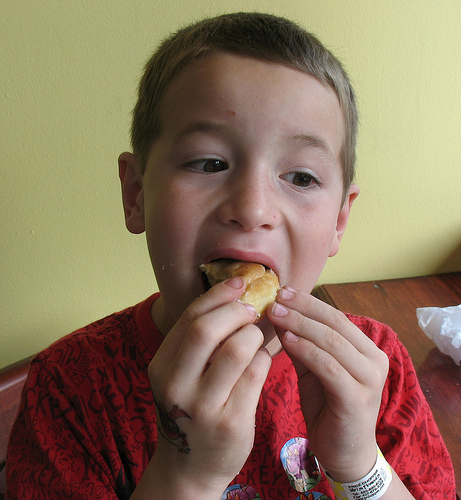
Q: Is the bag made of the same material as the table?
A: No, the bag is made of plastic and the table is made of wood.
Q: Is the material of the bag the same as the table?
A: No, the bag is made of plastic and the table is made of wood.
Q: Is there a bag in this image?
A: Yes, there is a bag.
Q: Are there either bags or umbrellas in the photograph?
A: Yes, there is a bag.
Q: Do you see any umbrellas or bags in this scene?
A: Yes, there is a bag.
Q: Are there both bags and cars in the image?
A: No, there is a bag but no cars.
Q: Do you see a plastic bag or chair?
A: Yes, there is a plastic bag.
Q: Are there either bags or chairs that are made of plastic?
A: Yes, the bag is made of plastic.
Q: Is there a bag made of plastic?
A: Yes, there is a bag that is made of plastic.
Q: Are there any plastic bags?
A: Yes, there is a bag that is made of plastic.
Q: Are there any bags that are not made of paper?
A: Yes, there is a bag that is made of plastic.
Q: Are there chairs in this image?
A: No, there are no chairs.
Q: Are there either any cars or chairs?
A: No, there are no chairs or cars.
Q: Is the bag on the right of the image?
A: Yes, the bag is on the right of the image.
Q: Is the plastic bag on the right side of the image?
A: Yes, the bag is on the right of the image.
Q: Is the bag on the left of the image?
A: No, the bag is on the right of the image.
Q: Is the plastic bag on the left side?
A: No, the bag is on the right of the image.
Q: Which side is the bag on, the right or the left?
A: The bag is on the right of the image.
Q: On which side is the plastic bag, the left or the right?
A: The bag is on the right of the image.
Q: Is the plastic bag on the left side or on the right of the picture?
A: The bag is on the right of the image.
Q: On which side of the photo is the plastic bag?
A: The bag is on the right of the image.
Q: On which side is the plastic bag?
A: The bag is on the right of the image.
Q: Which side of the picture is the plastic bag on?
A: The bag is on the right of the image.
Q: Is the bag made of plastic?
A: Yes, the bag is made of plastic.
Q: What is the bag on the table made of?
A: The bag is made of plastic.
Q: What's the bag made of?
A: The bag is made of plastic.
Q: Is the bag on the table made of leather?
A: No, the bag is made of plastic.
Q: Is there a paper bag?
A: No, there is a bag but it is made of plastic.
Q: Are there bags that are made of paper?
A: No, there is a bag but it is made of plastic.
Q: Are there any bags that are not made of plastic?
A: No, there is a bag but it is made of plastic.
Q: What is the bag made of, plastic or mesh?
A: The bag is made of plastic.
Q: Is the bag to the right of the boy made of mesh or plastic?
A: The bag is made of plastic.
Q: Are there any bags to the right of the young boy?
A: Yes, there is a bag to the right of the boy.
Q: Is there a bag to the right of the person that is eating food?
A: Yes, there is a bag to the right of the boy.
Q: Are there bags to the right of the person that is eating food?
A: Yes, there is a bag to the right of the boy.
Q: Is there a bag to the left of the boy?
A: No, the bag is to the right of the boy.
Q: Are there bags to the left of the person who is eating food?
A: No, the bag is to the right of the boy.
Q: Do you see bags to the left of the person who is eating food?
A: No, the bag is to the right of the boy.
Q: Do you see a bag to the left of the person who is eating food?
A: No, the bag is to the right of the boy.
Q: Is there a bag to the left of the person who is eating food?
A: No, the bag is to the right of the boy.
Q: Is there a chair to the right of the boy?
A: No, there is a bag to the right of the boy.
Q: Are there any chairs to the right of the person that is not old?
A: No, there is a bag to the right of the boy.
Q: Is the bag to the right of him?
A: Yes, the bag is to the right of the boy.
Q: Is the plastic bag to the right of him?
A: Yes, the bag is to the right of the boy.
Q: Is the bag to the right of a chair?
A: No, the bag is to the right of the boy.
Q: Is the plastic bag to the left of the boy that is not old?
A: No, the bag is to the right of the boy.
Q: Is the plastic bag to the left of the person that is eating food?
A: No, the bag is to the right of the boy.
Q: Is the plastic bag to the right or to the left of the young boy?
A: The bag is to the right of the boy.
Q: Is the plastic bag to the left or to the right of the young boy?
A: The bag is to the right of the boy.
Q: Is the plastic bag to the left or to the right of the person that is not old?
A: The bag is to the right of the boy.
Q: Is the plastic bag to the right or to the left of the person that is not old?
A: The bag is to the right of the boy.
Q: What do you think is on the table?
A: The bag is on the table.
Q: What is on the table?
A: The bag is on the table.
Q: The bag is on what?
A: The bag is on the table.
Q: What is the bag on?
A: The bag is on the table.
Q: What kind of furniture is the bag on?
A: The bag is on the table.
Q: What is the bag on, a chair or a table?
A: The bag is on a table.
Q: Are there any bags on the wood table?
A: Yes, there is a bag on the table.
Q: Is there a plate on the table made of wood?
A: No, there is a bag on the table.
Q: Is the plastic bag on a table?
A: Yes, the bag is on a table.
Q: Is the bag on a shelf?
A: No, the bag is on a table.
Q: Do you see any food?
A: Yes, there is food.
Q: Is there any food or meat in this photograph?
A: Yes, there is food.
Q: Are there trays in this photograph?
A: No, there are no trays.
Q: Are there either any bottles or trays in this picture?
A: No, there are no trays or bottles.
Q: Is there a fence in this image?
A: No, there are no fences.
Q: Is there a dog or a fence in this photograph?
A: No, there are no fences or dogs.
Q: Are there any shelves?
A: No, there are no shelves.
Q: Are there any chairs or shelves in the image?
A: No, there are no shelves or chairs.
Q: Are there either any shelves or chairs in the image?
A: No, there are no shelves or chairs.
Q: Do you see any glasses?
A: No, there are no glasses.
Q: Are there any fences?
A: No, there are no fences.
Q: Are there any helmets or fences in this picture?
A: No, there are no fences or helmets.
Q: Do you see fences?
A: No, there are no fences.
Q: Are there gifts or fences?
A: No, there are no fences or gifts.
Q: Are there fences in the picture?
A: No, there are no fences.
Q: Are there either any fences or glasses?
A: No, there are no fences or glasses.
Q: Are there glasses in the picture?
A: No, there are no glasses.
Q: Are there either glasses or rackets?
A: No, there are no glasses or rackets.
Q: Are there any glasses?
A: No, there are no glasses.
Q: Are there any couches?
A: No, there are no couches.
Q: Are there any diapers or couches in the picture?
A: No, there are no couches or diapers.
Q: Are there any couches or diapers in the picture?
A: No, there are no couches or diapers.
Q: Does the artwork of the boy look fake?
A: Yes, the artwork is fake.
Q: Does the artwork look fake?
A: Yes, the artwork is fake.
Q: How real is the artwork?
A: The artwork is fake.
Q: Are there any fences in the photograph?
A: No, there are no fences.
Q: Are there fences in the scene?
A: No, there are no fences.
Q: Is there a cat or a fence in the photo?
A: No, there are no fences or cats.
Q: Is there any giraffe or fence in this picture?
A: No, there are no fences or giraffes.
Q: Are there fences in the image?
A: No, there are no fences.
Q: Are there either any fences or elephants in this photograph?
A: No, there are no fences or elephants.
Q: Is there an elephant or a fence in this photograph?
A: No, there are no fences or elephants.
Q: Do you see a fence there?
A: No, there are no fences.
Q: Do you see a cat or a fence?
A: No, there are no fences or cats.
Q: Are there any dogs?
A: No, there are no dogs.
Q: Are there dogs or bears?
A: No, there are no dogs or bears.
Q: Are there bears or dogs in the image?
A: No, there are no dogs or bears.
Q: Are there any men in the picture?
A: No, there are no men.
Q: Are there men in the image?
A: No, there are no men.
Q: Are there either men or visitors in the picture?
A: No, there are no men or visitors.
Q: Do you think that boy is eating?
A: Yes, the boy is eating.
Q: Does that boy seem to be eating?
A: Yes, the boy is eating.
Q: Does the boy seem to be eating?
A: Yes, the boy is eating.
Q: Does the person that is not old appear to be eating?
A: Yes, the boy is eating.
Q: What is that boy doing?
A: The boy is eating.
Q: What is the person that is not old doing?
A: The boy is eating.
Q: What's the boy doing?
A: The boy is eating.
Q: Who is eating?
A: The boy is eating.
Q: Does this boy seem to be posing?
A: No, the boy is eating.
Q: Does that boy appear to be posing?
A: No, the boy is eating.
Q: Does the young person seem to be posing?
A: No, the boy is eating.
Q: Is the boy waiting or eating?
A: The boy is eating.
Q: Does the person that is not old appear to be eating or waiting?
A: The boy is eating.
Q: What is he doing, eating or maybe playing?
A: The boy is eating.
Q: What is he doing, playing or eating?
A: The boy is eating.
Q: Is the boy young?
A: Yes, the boy is young.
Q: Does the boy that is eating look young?
A: Yes, the boy is young.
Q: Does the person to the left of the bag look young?
A: Yes, the boy is young.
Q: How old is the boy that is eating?
A: The boy is young.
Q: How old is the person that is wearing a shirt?
A: The boy is young.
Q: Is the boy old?
A: No, the boy is young.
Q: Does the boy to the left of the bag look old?
A: No, the boy is young.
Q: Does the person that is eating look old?
A: No, the boy is young.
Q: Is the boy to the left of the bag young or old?
A: The boy is young.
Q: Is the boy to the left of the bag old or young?
A: The boy is young.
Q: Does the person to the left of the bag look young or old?
A: The boy is young.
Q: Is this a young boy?
A: Yes, this is a young boy.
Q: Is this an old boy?
A: No, this is a young boy.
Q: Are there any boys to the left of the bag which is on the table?
A: Yes, there is a boy to the left of the bag.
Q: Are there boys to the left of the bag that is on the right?
A: Yes, there is a boy to the left of the bag.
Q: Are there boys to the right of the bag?
A: No, the boy is to the left of the bag.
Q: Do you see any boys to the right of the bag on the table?
A: No, the boy is to the left of the bag.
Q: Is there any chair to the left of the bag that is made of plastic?
A: No, there is a boy to the left of the bag.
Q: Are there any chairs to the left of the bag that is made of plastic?
A: No, there is a boy to the left of the bag.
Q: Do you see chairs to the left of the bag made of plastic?
A: No, there is a boy to the left of the bag.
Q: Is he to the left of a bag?
A: Yes, the boy is to the left of a bag.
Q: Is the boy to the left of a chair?
A: No, the boy is to the left of a bag.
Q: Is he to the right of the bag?
A: No, the boy is to the left of the bag.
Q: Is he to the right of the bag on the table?
A: No, the boy is to the left of the bag.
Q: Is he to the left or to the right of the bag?
A: The boy is to the left of the bag.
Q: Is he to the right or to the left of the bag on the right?
A: The boy is to the left of the bag.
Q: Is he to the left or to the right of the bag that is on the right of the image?
A: The boy is to the left of the bag.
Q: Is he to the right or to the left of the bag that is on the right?
A: The boy is to the left of the bag.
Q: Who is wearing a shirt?
A: The boy is wearing a shirt.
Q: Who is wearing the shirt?
A: The boy is wearing a shirt.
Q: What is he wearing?
A: The boy is wearing a shirt.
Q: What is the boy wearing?
A: The boy is wearing a shirt.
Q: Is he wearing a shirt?
A: Yes, the boy is wearing a shirt.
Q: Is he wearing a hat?
A: No, the boy is wearing a shirt.